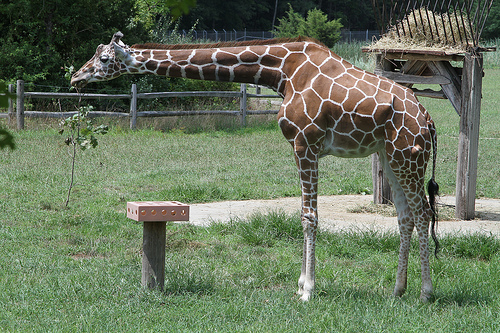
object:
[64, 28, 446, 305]
giraffe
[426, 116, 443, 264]
tail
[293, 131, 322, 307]
front leg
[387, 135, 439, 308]
back left leg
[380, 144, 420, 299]
back right leg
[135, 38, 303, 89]
neck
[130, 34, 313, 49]
mane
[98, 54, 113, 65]
eye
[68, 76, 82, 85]
nose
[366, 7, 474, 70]
hay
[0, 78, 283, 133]
fence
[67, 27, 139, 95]
head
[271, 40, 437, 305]
body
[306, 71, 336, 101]
spot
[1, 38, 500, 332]
grass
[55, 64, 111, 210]
tree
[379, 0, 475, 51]
grid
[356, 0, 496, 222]
feeder